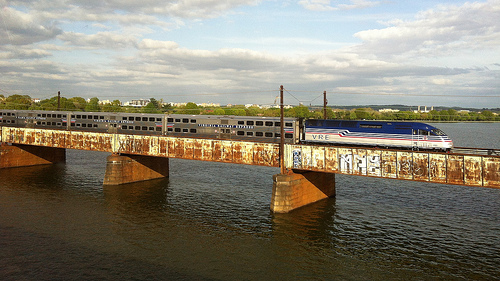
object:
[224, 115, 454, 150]
train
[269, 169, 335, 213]
pillar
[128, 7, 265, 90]
day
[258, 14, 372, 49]
sky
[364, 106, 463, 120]
tree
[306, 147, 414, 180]
bridge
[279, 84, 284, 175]
pole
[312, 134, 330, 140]
sign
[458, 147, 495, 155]
track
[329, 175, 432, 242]
water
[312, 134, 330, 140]
letter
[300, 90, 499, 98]
line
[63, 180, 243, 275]
river